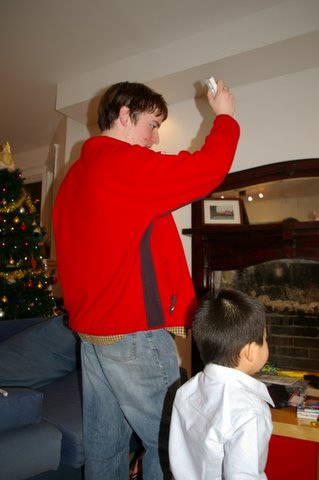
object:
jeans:
[79, 335, 185, 480]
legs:
[94, 330, 184, 479]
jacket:
[51, 112, 241, 344]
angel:
[0, 139, 17, 173]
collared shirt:
[167, 359, 280, 478]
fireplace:
[204, 243, 317, 372]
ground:
[266, 123, 279, 152]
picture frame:
[200, 196, 244, 229]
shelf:
[181, 222, 318, 233]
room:
[0, 0, 318, 478]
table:
[212, 303, 314, 479]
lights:
[247, 194, 253, 202]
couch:
[2, 301, 99, 477]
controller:
[205, 76, 216, 96]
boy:
[165, 288, 276, 479]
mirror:
[236, 175, 318, 226]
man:
[51, 80, 240, 480]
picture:
[202, 195, 243, 227]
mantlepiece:
[180, 216, 317, 251]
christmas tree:
[0, 140, 62, 319]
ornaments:
[10, 228, 26, 251]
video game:
[202, 42, 318, 414]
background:
[2, 34, 75, 474]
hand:
[205, 81, 236, 115]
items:
[288, 383, 306, 409]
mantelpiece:
[191, 158, 308, 225]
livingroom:
[14, 105, 63, 478]